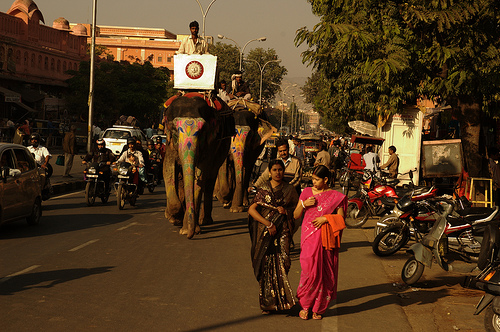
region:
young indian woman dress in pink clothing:
[291, 163, 348, 323]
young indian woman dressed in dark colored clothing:
[243, 157, 298, 313]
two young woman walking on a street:
[243, 158, 347, 320]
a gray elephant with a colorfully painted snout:
[163, 96, 233, 238]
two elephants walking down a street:
[162, 96, 252, 241]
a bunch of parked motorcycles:
[345, 165, 496, 289]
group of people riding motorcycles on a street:
[75, 136, 161, 212]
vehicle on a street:
[1, 142, 46, 238]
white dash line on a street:
[4, 258, 39, 278]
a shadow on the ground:
[0, 257, 120, 299]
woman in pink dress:
[289, 159, 354, 314]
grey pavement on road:
[144, 254, 221, 313]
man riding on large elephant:
[164, 15, 237, 240]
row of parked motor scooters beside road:
[370, 192, 497, 329]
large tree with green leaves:
[306, 3, 498, 108]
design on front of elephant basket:
[180, 58, 212, 83]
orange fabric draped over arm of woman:
[313, 209, 355, 260]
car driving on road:
[0, 139, 52, 234]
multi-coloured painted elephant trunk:
[171, 111, 208, 224]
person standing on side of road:
[51, 110, 82, 185]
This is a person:
[291, 160, 353, 327]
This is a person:
[247, 156, 296, 317]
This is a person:
[276, 140, 307, 206]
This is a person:
[448, 162, 479, 247]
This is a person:
[410, 168, 450, 234]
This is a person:
[380, 138, 405, 206]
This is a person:
[361, 135, 382, 177]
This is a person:
[339, 128, 356, 175]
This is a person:
[111, 134, 145, 209]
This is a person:
[81, 133, 116, 208]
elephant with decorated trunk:
[154, 99, 229, 245]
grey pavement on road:
[115, 242, 220, 330]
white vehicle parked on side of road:
[84, 116, 154, 156]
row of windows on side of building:
[0, 40, 80, 87]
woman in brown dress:
[234, 156, 303, 330]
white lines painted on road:
[26, 223, 151, 300]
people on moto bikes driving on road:
[64, 116, 168, 228]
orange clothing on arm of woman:
[314, 210, 359, 257]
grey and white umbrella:
[340, 115, 387, 145]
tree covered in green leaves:
[94, 53, 163, 120]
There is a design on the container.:
[163, 49, 233, 103]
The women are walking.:
[251, 150, 384, 310]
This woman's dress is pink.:
[294, 167, 344, 319]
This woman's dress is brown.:
[233, 155, 295, 308]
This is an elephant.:
[148, 88, 230, 235]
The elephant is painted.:
[146, 95, 226, 226]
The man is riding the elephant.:
[166, 6, 230, 143]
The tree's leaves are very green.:
[323, 7, 487, 109]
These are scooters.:
[368, 173, 489, 302]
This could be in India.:
[37, 24, 462, 318]